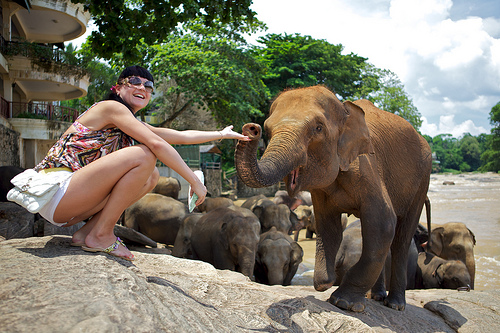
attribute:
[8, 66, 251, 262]
woman — holding, pausing, smiling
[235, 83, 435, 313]
elephant — baby, brown, young, playing, eating, walking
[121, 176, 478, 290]
elephants — brown, bunch, playing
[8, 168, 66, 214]
purse — white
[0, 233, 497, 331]
rock — gray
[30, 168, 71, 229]
shorts — white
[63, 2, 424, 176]
trees — green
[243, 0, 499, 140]
sky — blue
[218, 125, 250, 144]
hand — stretched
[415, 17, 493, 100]
clouds — white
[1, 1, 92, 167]
building — in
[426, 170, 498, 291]
river — in